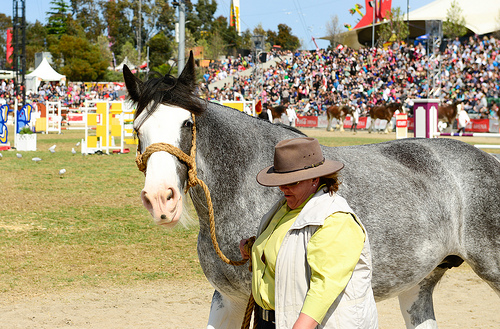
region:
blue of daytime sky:
[1, 0, 428, 50]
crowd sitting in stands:
[203, 41, 496, 112]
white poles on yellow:
[81, 100, 255, 152]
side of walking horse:
[125, 57, 498, 327]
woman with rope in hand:
[240, 136, 370, 328]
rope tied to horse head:
[134, 101, 226, 261]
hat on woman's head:
[256, 136, 344, 188]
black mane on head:
[137, 72, 201, 112]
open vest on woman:
[247, 192, 373, 327]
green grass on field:
[2, 135, 427, 283]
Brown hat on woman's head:
[251, 130, 345, 186]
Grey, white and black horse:
[125, 62, 498, 325]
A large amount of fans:
[199, 34, 496, 110]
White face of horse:
[130, 102, 195, 224]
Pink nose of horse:
[134, 179, 186, 223]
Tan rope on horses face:
[121, 104, 246, 274]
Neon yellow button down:
[231, 202, 357, 320]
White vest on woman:
[244, 196, 384, 326]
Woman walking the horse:
[231, 130, 376, 327]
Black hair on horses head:
[114, 46, 206, 113]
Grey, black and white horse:
[119, 58, 494, 325]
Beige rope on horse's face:
[131, 112, 237, 278]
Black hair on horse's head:
[121, 45, 201, 112]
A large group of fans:
[209, 35, 499, 111]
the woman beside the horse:
[227, 135, 379, 320]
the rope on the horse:
[130, 144, 215, 198]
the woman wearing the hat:
[240, 123, 352, 183]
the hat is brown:
[254, 136, 351, 188]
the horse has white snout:
[120, 95, 211, 222]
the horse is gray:
[128, 49, 498, 317]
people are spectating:
[244, 39, 499, 97]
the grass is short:
[7, 178, 157, 279]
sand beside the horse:
[24, 283, 203, 328]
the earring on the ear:
[312, 182, 318, 187]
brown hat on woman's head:
[249, 133, 358, 198]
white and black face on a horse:
[118, 50, 207, 230]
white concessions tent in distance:
[25, 54, 67, 90]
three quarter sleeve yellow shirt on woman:
[283, 209, 368, 321]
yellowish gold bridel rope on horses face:
[128, 135, 203, 184]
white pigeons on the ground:
[7, 152, 76, 177]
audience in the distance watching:
[280, 30, 457, 90]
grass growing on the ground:
[27, 219, 139, 274]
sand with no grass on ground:
[46, 294, 176, 325]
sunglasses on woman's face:
[275, 182, 309, 189]